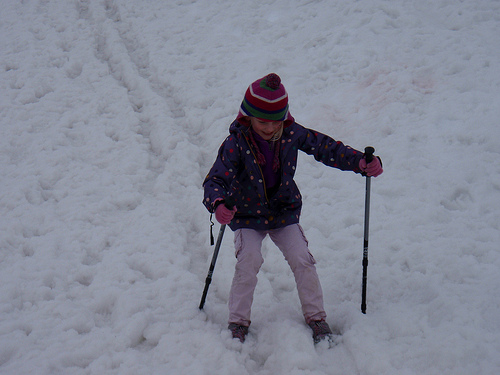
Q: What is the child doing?
A: Skiing.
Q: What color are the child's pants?
A: Pink.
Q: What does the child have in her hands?
A: Ski poles.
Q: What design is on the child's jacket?
A: Polka-dots.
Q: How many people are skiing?
A: One.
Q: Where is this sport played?
A: In the snow.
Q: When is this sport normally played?
A: Winter.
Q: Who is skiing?
A: A child.